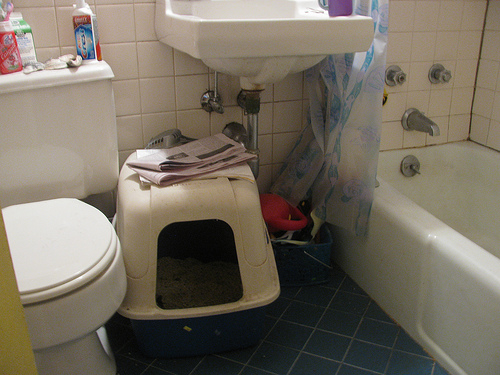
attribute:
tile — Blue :
[245, 339, 305, 371]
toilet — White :
[2, 60, 149, 371]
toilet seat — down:
[0, 55, 128, 373]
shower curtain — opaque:
[267, 0, 388, 241]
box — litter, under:
[105, 149, 285, 360]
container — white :
[1, 28, 22, 75]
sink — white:
[155, 2, 371, 85]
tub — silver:
[338, 139, 499, 373]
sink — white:
[150, 2, 380, 92]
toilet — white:
[2, 59, 132, 373]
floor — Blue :
[103, 257, 451, 373]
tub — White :
[384, 147, 496, 342]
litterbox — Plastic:
[126, 165, 280, 315]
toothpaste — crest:
[48, 8, 101, 54]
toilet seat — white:
[0, 197, 119, 307]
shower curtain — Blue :
[306, 3, 389, 306]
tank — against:
[9, 52, 136, 193]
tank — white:
[1, 54, 122, 211]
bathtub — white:
[344, 139, 499, 361]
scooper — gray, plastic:
[145, 121, 193, 153]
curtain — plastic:
[271, 17, 406, 231]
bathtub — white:
[330, 141, 498, 371]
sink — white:
[145, 3, 400, 123]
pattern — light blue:
[316, 64, 344, 137]